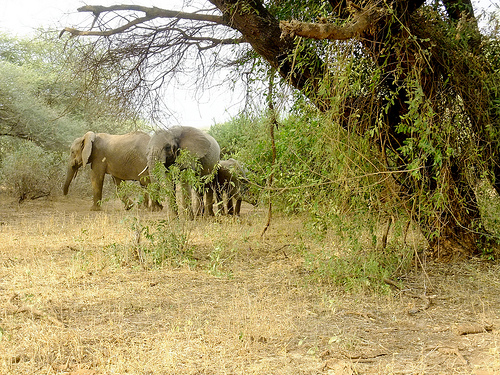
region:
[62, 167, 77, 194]
gray elephant's trunk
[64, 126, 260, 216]
three gray elephants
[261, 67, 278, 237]
brown hanging tree branch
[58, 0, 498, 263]
trees with branches and green leaves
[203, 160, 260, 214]
small elephant next to large elephants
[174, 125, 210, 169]
large elephant ear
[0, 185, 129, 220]
shade from large nearby tree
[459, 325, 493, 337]
stick on ground by tree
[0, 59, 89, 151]
partial green tree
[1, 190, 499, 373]
brown dry grass clearing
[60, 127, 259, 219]
three gray elephants walking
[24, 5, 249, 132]
tree branches hanging over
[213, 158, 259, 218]
young elephant with larger elephants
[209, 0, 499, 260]
brown tree trunk near the elephants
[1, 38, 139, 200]
large green tree in the background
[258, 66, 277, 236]
tree branch hanging from tree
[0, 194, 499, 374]
big patch of dry grass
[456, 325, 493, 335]
stick laying on the dry grass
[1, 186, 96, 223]
shade from the tall tree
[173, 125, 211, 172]
large gray elephant ear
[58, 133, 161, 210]
medium sized elephant in the group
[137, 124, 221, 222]
largest sized elephant in the group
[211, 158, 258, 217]
baby elephant stands besides adult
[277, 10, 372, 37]
broken branch hanging from the closes tree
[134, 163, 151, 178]
elephant ivory tusk from the largest one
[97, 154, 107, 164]
left elephant has a scare in its side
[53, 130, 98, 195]
elephant eating from the srub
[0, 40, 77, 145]
large willow three to the left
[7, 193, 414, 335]
clearing in the forest with a few srubs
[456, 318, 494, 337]
dead branch fallen to the ground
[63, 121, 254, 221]
trio of grey elephants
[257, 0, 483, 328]
patch of vines hanging off tree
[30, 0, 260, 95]
dead branches on tree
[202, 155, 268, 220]
smaller elephant of trio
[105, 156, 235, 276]
tall weeds in dead grass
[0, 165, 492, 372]
dead grass covering ground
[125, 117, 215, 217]
male grey elephant with tusks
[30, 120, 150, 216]
female grey elephant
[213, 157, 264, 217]
youngest grey elephant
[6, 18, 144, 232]
wirey green tree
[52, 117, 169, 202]
a small elephant in a forest.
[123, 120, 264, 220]
a small elephant on a road.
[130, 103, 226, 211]
an elephant in a field.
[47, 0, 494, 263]
a tree with dry branches.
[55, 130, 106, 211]
an elephant with a long trunk.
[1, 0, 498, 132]
a hazy gray sky.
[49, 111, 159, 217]
a small elephant with a trunk.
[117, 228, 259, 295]
plants growing out of the ground.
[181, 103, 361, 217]
leafy green bushes.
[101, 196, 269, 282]
green plants on the road.